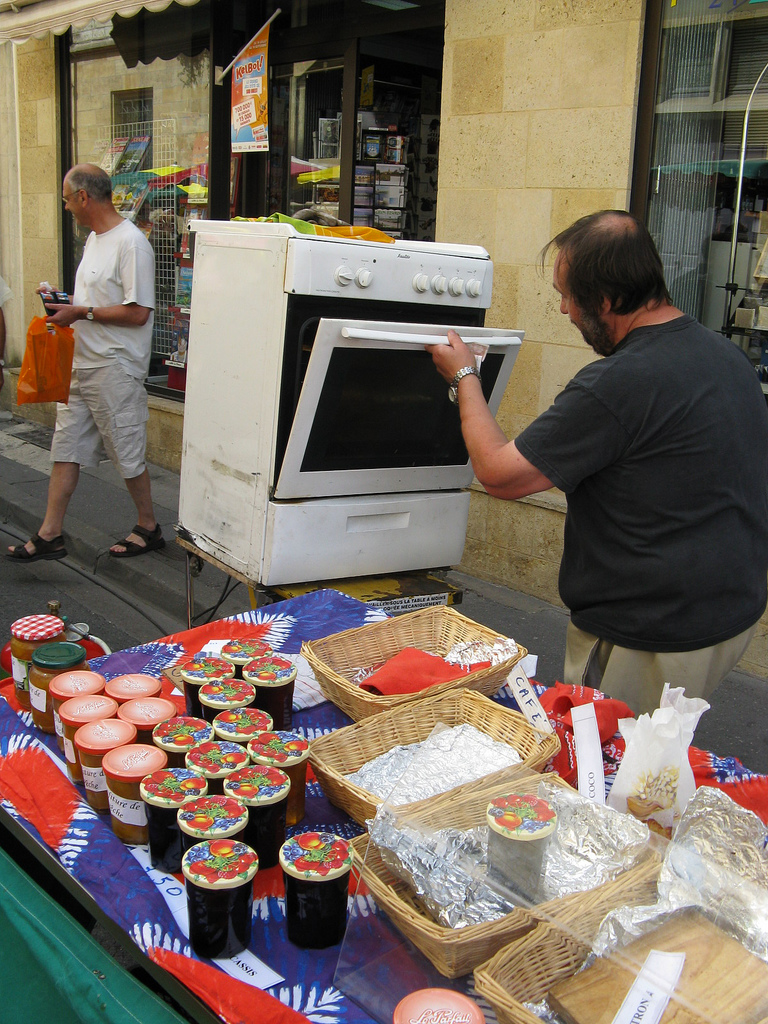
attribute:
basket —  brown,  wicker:
[294, 599, 527, 716]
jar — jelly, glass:
[177, 792, 249, 846]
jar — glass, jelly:
[139, 763, 208, 873]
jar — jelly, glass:
[221, 761, 293, 867]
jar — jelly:
[97, 742, 171, 842]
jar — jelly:
[72, 717, 140, 811]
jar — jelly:
[24, 640, 88, 730]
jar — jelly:
[9, 613, 69, 705]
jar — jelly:
[179, 657, 236, 718]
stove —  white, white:
[178, 218, 521, 582]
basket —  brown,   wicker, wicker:
[299, 605, 529, 725]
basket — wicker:
[310, 687, 562, 828]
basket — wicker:
[346, 770, 662, 978]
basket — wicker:
[477, 859, 763, 1018]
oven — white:
[176, 220, 525, 585]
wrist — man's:
[440, 370, 480, 385]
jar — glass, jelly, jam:
[279, 828, 354, 948]